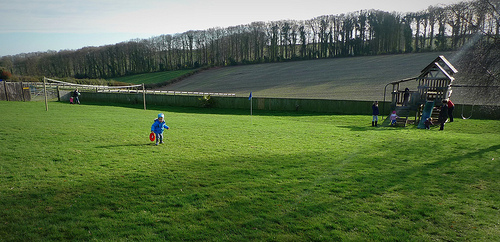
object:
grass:
[1, 98, 499, 240]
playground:
[379, 54, 457, 129]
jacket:
[150, 118, 168, 134]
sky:
[0, 0, 499, 57]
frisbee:
[148, 132, 156, 142]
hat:
[157, 112, 164, 119]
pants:
[155, 133, 164, 144]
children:
[150, 112, 171, 146]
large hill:
[91, 49, 498, 103]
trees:
[407, 11, 428, 54]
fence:
[75, 78, 394, 116]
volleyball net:
[42, 76, 148, 111]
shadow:
[0, 144, 499, 241]